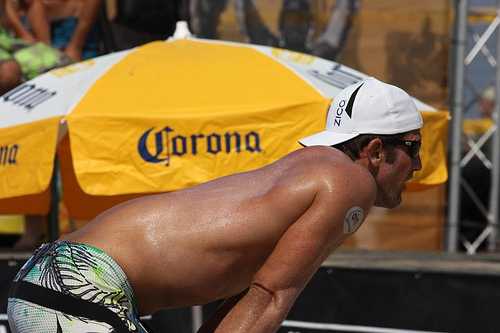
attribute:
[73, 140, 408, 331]
man — young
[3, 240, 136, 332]
shorts — board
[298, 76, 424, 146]
cap — baseball, backwards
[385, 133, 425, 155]
sunglasses — black, dark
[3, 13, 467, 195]
umbrella — white, yellow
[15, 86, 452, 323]
man — toned, atheletic, young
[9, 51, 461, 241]
umbrella — white, yellow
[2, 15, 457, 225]
umbrella — yellow, sponsored, sports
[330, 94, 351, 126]
lettering — black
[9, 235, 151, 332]
trunks — white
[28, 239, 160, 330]
trunks — multi-color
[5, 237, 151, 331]
shorts — multicolored, athletic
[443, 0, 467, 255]
pole — gray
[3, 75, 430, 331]
man — physically fit, tan, young, leaning forward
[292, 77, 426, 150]
cap — white, baseball, sponsored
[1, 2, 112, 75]
people — sitting, in distance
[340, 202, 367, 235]
tattoo — temporary, of sponser